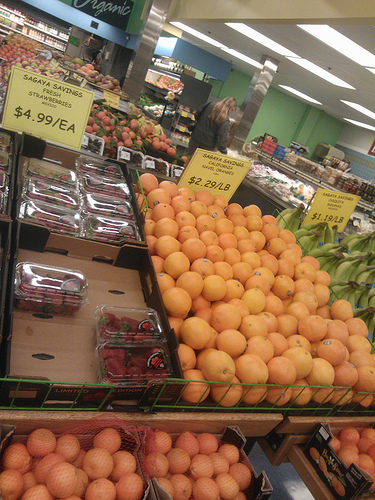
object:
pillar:
[227, 53, 279, 154]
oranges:
[0, 439, 33, 473]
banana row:
[304, 247, 375, 285]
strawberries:
[98, 345, 128, 365]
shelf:
[0, 126, 374, 411]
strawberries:
[42, 207, 52, 219]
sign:
[13, 71, 84, 134]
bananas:
[338, 227, 371, 255]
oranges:
[275, 309, 299, 338]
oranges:
[200, 270, 227, 303]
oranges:
[179, 234, 207, 263]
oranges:
[152, 232, 182, 258]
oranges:
[189, 256, 215, 281]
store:
[0, 0, 375, 497]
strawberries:
[102, 353, 129, 383]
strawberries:
[96, 310, 117, 328]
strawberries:
[57, 291, 82, 315]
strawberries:
[99, 323, 117, 341]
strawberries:
[124, 225, 134, 240]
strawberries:
[43, 216, 66, 229]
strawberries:
[114, 203, 124, 211]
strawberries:
[141, 363, 170, 381]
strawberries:
[124, 353, 151, 370]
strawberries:
[26, 283, 47, 308]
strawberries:
[106, 200, 119, 210]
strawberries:
[32, 183, 44, 193]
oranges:
[25, 425, 57, 458]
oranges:
[337, 424, 361, 444]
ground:
[247, 440, 313, 498]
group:
[131, 169, 374, 407]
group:
[321, 422, 375, 482]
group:
[142, 424, 253, 498]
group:
[0, 425, 145, 498]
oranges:
[336, 445, 360, 468]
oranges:
[144, 427, 173, 455]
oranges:
[80, 445, 113, 480]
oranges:
[242, 202, 263, 217]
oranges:
[344, 330, 373, 355]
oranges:
[209, 373, 243, 408]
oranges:
[314, 335, 346, 367]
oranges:
[331, 357, 359, 387]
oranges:
[237, 311, 270, 340]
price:
[13, 103, 76, 136]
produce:
[0, 30, 374, 498]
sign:
[186, 150, 247, 192]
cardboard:
[1, 219, 186, 406]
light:
[219, 47, 264, 72]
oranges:
[263, 233, 287, 256]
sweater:
[186, 98, 229, 156]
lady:
[185, 94, 238, 159]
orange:
[149, 201, 174, 224]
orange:
[144, 186, 173, 208]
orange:
[170, 193, 191, 215]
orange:
[194, 188, 215, 207]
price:
[185, 173, 231, 193]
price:
[309, 210, 345, 225]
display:
[127, 167, 375, 409]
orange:
[265, 353, 297, 385]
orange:
[270, 272, 297, 300]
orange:
[302, 353, 335, 388]